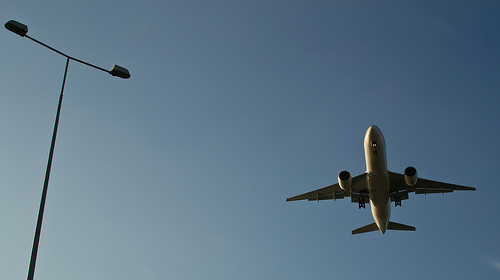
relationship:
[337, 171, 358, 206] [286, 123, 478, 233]
jet engine on passenger jet